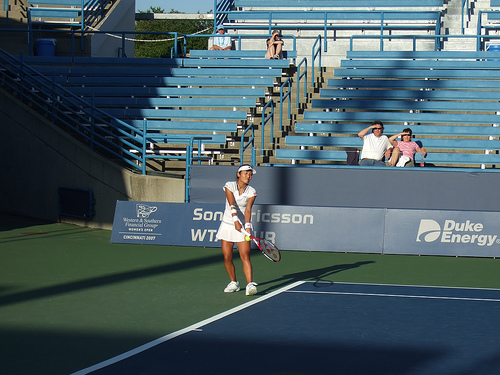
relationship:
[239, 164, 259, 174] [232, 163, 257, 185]
visor on a head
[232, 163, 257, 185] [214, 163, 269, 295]
head of player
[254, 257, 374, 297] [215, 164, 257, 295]
shadow of player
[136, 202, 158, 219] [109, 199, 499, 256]
graphic on  a wall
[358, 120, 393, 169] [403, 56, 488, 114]
man sitting in stands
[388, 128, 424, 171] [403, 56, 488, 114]
people sitting in stands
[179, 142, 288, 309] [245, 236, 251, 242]
asian woman playing ball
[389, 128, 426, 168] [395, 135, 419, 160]
people in a shirt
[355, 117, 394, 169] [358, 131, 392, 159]
man in shirt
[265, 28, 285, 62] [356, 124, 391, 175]
man in shirt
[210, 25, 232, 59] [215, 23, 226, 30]
man in hat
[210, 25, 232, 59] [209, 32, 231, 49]
man in shirt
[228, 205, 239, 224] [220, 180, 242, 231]
objects around woman's arm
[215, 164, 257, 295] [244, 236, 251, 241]
player holding ball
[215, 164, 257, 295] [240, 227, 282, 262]
player holding racket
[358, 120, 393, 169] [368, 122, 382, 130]
man shading eyes right hand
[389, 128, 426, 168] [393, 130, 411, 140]
people shading eyes right hand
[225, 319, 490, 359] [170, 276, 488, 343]
part of a court